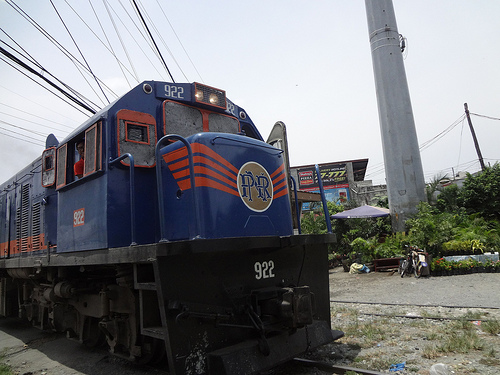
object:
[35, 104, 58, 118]
white clouds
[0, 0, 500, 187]
blue sky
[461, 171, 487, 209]
trees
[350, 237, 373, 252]
bushes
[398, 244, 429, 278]
bicycle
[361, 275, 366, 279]
sand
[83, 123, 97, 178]
windows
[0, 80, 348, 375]
train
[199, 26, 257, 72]
clouds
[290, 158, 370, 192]
billboard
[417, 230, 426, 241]
plants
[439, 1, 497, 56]
clouds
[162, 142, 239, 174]
lines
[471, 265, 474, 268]
orange flowers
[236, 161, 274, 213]
logo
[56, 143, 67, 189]
window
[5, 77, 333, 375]
engine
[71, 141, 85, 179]
man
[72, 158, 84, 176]
shirt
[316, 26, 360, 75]
clouds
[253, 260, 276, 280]
922